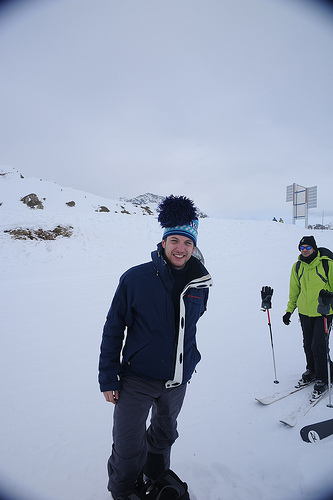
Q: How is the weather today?
A: It is cloudy.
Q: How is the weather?
A: It is cloudy.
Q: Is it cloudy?
A: Yes, it is cloudy.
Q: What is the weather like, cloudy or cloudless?
A: It is cloudy.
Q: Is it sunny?
A: No, it is cloudy.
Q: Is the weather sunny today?
A: No, it is cloudy.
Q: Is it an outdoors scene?
A: Yes, it is outdoors.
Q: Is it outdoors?
A: Yes, it is outdoors.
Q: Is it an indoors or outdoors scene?
A: It is outdoors.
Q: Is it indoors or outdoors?
A: It is outdoors.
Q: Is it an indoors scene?
A: No, it is outdoors.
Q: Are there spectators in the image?
A: No, there are no spectators.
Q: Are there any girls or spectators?
A: No, there are no spectators or girls.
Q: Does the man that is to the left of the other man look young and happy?
A: Yes, the man is young and happy.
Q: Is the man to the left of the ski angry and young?
A: No, the man is young but happy.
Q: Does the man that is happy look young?
A: Yes, the man is young.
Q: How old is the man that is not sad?
A: The man is young.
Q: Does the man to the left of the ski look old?
A: No, the man is young.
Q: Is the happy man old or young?
A: The man is young.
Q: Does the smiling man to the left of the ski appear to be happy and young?
A: Yes, the man is happy and young.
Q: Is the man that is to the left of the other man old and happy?
A: No, the man is happy but young.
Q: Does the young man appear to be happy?
A: Yes, the man is happy.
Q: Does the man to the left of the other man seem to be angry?
A: No, the man is happy.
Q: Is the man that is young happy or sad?
A: The man is happy.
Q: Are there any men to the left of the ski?
A: Yes, there is a man to the left of the ski.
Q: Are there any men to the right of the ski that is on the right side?
A: No, the man is to the left of the ski.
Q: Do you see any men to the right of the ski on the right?
A: No, the man is to the left of the ski.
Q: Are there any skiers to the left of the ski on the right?
A: No, there is a man to the left of the ski.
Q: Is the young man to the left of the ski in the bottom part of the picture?
A: Yes, the man is to the left of the ski.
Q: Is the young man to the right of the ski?
A: No, the man is to the left of the ski.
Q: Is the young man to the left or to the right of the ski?
A: The man is to the left of the ski.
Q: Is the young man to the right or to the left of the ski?
A: The man is to the left of the ski.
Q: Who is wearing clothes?
A: The man is wearing clothes.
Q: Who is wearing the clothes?
A: The man is wearing clothes.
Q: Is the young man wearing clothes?
A: Yes, the man is wearing clothes.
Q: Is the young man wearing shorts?
A: No, the man is wearing clothes.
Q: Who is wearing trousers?
A: The man is wearing trousers.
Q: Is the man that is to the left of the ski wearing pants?
A: Yes, the man is wearing pants.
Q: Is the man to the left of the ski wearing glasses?
A: No, the man is wearing pants.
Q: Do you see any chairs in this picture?
A: No, there are no chairs.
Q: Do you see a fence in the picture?
A: No, there are no fences.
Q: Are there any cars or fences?
A: No, there are no fences or cars.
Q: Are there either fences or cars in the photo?
A: No, there are no fences or cars.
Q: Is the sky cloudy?
A: Yes, the sky is cloudy.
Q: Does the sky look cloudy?
A: Yes, the sky is cloudy.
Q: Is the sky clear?
A: No, the sky is cloudy.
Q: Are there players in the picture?
A: No, there are no players.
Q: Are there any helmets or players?
A: No, there are no players or helmets.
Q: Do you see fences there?
A: No, there are no fences.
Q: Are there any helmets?
A: No, there are no helmets.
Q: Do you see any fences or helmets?
A: No, there are no fences or helmets.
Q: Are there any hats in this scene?
A: Yes, there is a hat.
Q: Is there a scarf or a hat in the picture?
A: Yes, there is a hat.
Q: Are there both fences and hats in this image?
A: No, there is a hat but no fences.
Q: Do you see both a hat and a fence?
A: No, there is a hat but no fences.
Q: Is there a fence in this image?
A: No, there are no fences.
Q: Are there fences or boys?
A: No, there are no fences or boys.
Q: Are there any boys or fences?
A: No, there are no fences or boys.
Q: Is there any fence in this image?
A: No, there are no fences.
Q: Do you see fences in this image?
A: No, there are no fences.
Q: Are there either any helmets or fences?
A: No, there are no fences or helmets.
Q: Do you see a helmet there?
A: No, there are no helmets.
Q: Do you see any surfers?
A: No, there are no surfers.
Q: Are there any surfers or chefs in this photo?
A: No, there are no surfers or chefs.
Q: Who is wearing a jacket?
A: The man is wearing a jacket.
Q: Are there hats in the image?
A: Yes, there is a hat.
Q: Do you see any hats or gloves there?
A: Yes, there is a hat.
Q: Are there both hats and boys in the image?
A: No, there is a hat but no boys.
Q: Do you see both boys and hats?
A: No, there is a hat but no boys.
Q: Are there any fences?
A: No, there are no fences.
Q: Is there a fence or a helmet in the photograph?
A: No, there are no fences or helmets.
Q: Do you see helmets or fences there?
A: No, there are no fences or helmets.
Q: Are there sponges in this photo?
A: No, there are no sponges.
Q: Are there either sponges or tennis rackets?
A: No, there are no sponges or tennis rackets.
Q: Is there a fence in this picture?
A: No, there are no fences.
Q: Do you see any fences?
A: No, there are no fences.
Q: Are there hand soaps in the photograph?
A: No, there are no hand soaps.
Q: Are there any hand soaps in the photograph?
A: No, there are no hand soaps.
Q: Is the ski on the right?
A: Yes, the ski is on the right of the image.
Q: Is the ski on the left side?
A: No, the ski is on the right of the image.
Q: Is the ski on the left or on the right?
A: The ski is on the right of the image.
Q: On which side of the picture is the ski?
A: The ski is on the right of the image.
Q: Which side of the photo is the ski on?
A: The ski is on the right of the image.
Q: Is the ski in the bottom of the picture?
A: Yes, the ski is in the bottom of the image.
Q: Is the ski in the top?
A: No, the ski is in the bottom of the image.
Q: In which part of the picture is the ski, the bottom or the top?
A: The ski is in the bottom of the image.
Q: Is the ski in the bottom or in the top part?
A: The ski is in the bottom of the image.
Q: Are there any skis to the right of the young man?
A: Yes, there is a ski to the right of the man.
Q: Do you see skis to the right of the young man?
A: Yes, there is a ski to the right of the man.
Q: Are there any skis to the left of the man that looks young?
A: No, the ski is to the right of the man.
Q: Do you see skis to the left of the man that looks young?
A: No, the ski is to the right of the man.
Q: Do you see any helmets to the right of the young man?
A: No, there is a ski to the right of the man.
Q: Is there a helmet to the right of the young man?
A: No, there is a ski to the right of the man.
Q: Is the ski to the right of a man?
A: Yes, the ski is to the right of a man.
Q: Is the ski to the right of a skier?
A: No, the ski is to the right of a man.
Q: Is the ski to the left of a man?
A: No, the ski is to the right of a man.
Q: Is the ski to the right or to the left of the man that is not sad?
A: The ski is to the right of the man.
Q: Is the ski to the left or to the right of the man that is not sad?
A: The ski is to the right of the man.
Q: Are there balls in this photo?
A: Yes, there is a ball.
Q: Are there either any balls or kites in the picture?
A: Yes, there is a ball.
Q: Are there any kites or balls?
A: Yes, there is a ball.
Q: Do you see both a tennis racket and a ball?
A: No, there is a ball but no rackets.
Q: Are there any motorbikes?
A: No, there are no motorbikes.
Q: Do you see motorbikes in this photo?
A: No, there are no motorbikes.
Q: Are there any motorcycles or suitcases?
A: No, there are no motorcycles or suitcases.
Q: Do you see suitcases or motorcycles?
A: No, there are no motorcycles or suitcases.